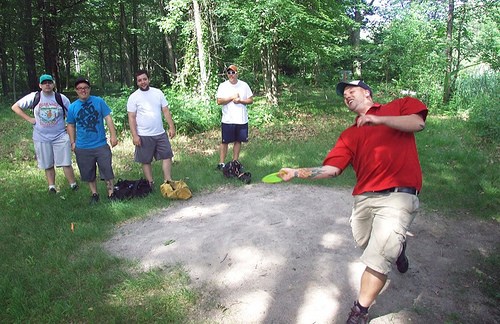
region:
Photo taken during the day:
[17, 17, 492, 313]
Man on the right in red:
[307, 71, 427, 316]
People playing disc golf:
[12, 66, 429, 316]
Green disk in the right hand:
[250, 170, 292, 185]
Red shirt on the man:
[312, 100, 434, 189]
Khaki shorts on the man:
[345, 175, 425, 284]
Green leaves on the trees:
[29, 11, 420, 108]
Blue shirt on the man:
[66, 94, 116, 148]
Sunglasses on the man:
[227, 69, 242, 75]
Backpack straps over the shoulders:
[17, 94, 69, 111]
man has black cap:
[330, 57, 377, 122]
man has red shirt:
[280, 125, 457, 233]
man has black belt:
[352, 167, 460, 234]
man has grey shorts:
[338, 198, 439, 275]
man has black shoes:
[401, 234, 421, 298]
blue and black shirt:
[58, 97, 109, 151]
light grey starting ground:
[147, 211, 362, 322]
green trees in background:
[210, 11, 465, 139]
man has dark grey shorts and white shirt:
[123, 130, 173, 167]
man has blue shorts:
[227, 101, 267, 161]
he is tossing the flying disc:
[243, 59, 463, 321]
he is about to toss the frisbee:
[250, 62, 485, 321]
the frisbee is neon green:
[254, 155, 299, 191]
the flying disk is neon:
[260, 163, 299, 186]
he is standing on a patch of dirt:
[240, 57, 443, 322]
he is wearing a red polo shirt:
[308, 45, 498, 240]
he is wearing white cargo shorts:
[334, 179, 429, 281]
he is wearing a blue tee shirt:
[55, 62, 133, 233]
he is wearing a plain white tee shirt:
[115, 52, 196, 187]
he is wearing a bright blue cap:
[6, 57, 75, 198]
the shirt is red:
[321, 98, 442, 200]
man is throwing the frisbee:
[218, 39, 461, 306]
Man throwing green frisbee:
[259, 72, 429, 322]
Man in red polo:
[278, 75, 430, 322]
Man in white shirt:
[213, 61, 251, 169]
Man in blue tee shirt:
[67, 75, 117, 201]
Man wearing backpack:
[10, 73, 72, 193]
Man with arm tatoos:
[274, 78, 432, 323]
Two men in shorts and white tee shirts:
[125, 63, 252, 189]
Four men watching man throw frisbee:
[6, 60, 426, 321]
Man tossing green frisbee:
[257, 71, 425, 321]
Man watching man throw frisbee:
[206, 54, 433, 320]